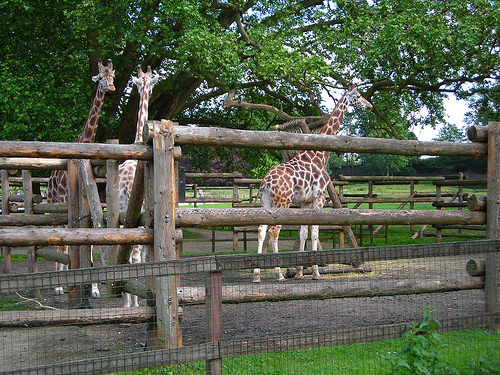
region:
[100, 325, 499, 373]
healthy grassy green lawn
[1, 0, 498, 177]
huge big tree with many branches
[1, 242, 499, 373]
net below the fence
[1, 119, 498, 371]
wooden high look through fence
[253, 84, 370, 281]
tall giraffe with brown spots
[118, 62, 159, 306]
brown tall giraffe backig camera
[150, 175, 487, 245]
green wide huge lawn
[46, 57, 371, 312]
three giraffes in a park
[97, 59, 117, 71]
anthers on tall giraffes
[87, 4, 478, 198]
branches on huge tree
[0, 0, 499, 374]
a zoo's giraffe exhibit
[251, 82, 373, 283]
a giraffe at the zoo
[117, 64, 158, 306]
a giraffe at the zoo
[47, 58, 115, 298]
a giraffe at the zoo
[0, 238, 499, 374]
a wood and metal fence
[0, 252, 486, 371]
a large patch of dirt on the ground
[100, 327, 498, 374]
a patch of green grass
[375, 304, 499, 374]
green bushes on the ground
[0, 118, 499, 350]
a series of wooden fences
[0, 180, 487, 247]
a field of green grass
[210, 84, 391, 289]
single giraffe standing alone in a zoo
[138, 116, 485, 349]
large wooden fence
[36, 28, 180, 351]
Two giraffes standing up together.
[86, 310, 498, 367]
small patch of green grass and weeds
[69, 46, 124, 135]
Single giraffe head surrounded by leaves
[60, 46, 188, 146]
two giraffe heads surrounded by leaves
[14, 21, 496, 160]
very large and very old tree with green leaves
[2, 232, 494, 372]
mesh metal screens along the bottom of a fence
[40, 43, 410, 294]
three giraffes grazing on leaves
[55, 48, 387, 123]
three giraffe heads with trees in the background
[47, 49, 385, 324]
giraffes in wood fence enclosure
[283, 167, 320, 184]
brown spots on giraffe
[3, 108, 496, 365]
wooden fence surrounding giraffes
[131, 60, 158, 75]
ossicones on giraffe head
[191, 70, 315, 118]
tree branch on tree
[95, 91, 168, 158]
tree trunk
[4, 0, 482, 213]
tall tree behind wood fence enclosure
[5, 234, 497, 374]
metal fence attached to wooden support poles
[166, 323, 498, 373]
green grass on ground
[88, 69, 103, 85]
giraffe ears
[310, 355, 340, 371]
the grass is green and low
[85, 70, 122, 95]
the giraffes face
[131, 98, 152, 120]
the giraffes neck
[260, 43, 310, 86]
the leaves on the tree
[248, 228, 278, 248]
giraffes legs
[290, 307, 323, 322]
the dirt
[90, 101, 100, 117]
the giraffes neck is long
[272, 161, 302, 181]
the skin of the giraffe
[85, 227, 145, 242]
a log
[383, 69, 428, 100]
the tree branches